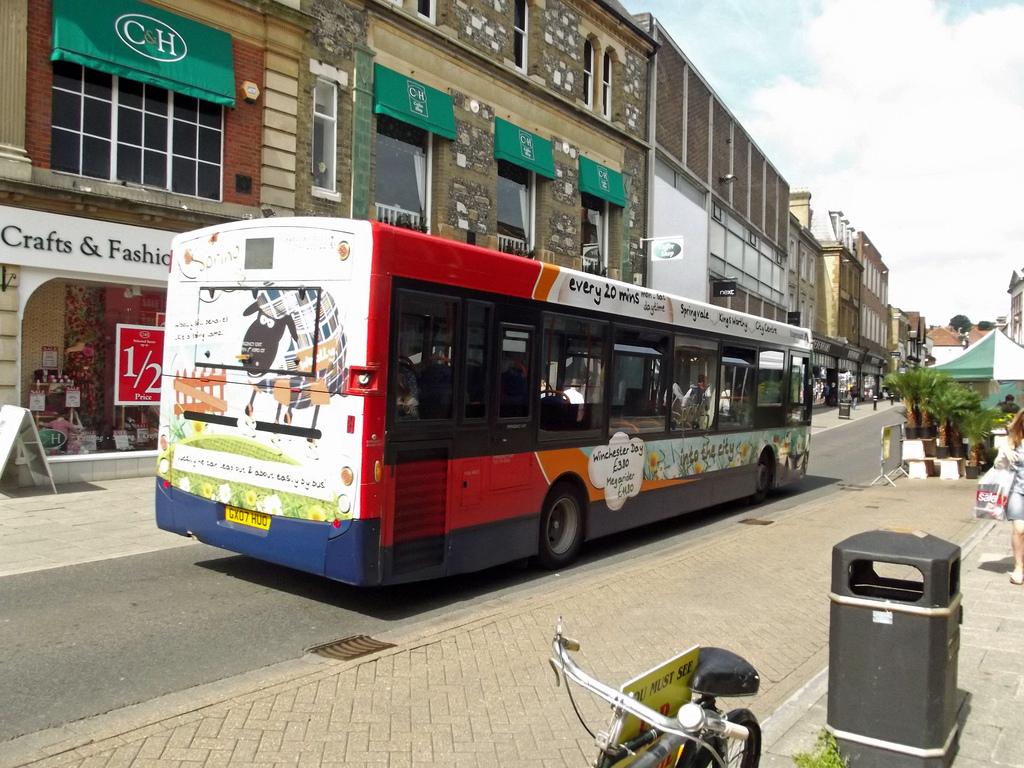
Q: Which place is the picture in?
A: It is at the street.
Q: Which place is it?
A: It is a street.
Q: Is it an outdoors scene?
A: Yes, it is outdoors.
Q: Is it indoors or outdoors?
A: It is outdoors.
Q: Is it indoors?
A: No, it is outdoors.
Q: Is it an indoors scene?
A: No, it is outdoors.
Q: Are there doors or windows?
A: Yes, there are windows.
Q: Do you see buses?
A: Yes, there is a bus.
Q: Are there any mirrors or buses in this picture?
A: Yes, there is a bus.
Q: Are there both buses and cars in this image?
A: No, there is a bus but no cars.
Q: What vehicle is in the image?
A: The vehicle is a bus.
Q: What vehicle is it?
A: The vehicle is a bus.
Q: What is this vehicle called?
A: This is a bus.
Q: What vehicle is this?
A: This is a bus.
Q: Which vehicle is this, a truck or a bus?
A: This is a bus.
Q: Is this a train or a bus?
A: This is a bus.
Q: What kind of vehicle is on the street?
A: The vehicle is a bus.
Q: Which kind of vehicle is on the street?
A: The vehicle is a bus.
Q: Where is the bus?
A: The bus is on the street.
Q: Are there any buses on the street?
A: Yes, there is a bus on the street.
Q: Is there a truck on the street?
A: No, there is a bus on the street.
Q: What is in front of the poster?
A: The bus is in front of the poster.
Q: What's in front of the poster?
A: The bus is in front of the poster.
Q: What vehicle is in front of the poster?
A: The vehicle is a bus.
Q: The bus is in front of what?
A: The bus is in front of the poster.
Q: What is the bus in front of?
A: The bus is in front of the poster.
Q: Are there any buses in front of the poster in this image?
A: Yes, there is a bus in front of the poster.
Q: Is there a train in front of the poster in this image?
A: No, there is a bus in front of the poster.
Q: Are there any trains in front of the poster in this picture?
A: No, there is a bus in front of the poster.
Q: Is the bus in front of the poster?
A: Yes, the bus is in front of the poster.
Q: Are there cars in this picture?
A: No, there are no cars.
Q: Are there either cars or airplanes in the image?
A: No, there are no cars or airplanes.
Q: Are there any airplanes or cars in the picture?
A: No, there are no cars or airplanes.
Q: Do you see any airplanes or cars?
A: No, there are no cars or airplanes.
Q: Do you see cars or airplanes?
A: No, there are no cars or airplanes.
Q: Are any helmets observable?
A: No, there are no helmets.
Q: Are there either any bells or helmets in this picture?
A: No, there are no helmets or bells.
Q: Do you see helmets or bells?
A: No, there are no helmets or bells.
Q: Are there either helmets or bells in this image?
A: No, there are no helmets or bells.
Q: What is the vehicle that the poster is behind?
A: The vehicle is a bus.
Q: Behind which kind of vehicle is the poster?
A: The poster is behind the bus.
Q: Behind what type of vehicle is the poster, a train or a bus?
A: The poster is behind a bus.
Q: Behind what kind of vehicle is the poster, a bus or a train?
A: The poster is behind a bus.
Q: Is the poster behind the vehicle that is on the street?
A: Yes, the poster is behind the bus.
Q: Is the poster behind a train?
A: No, the poster is behind the bus.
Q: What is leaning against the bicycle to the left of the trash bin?
A: The sign is leaning against the bicycle.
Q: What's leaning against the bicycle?
A: The sign is leaning against the bicycle.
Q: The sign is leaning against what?
A: The sign is leaning against the bicycle.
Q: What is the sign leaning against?
A: The sign is leaning against the bicycle.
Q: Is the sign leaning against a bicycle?
A: Yes, the sign is leaning against a bicycle.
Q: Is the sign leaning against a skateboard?
A: No, the sign is leaning against a bicycle.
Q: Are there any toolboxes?
A: No, there are no toolboxes.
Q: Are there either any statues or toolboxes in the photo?
A: No, there are no toolboxes or statues.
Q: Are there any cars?
A: No, there are no cars.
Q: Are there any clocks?
A: No, there are no clocks.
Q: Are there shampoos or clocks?
A: No, there are no clocks or shampoos.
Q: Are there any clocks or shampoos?
A: No, there are no clocks or shampoos.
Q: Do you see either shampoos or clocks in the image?
A: No, there are no clocks or shampoos.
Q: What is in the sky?
A: The clouds are in the sky.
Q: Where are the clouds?
A: The clouds are in the sky.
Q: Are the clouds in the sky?
A: Yes, the clouds are in the sky.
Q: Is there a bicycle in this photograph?
A: Yes, there is a bicycle.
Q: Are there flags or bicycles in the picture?
A: Yes, there is a bicycle.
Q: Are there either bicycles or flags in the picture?
A: Yes, there is a bicycle.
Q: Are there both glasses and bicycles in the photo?
A: No, there is a bicycle but no glasses.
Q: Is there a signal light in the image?
A: No, there are no traffic lights.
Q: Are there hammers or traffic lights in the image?
A: No, there are no traffic lights or hammers.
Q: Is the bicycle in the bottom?
A: Yes, the bicycle is in the bottom of the image.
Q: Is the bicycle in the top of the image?
A: No, the bicycle is in the bottom of the image.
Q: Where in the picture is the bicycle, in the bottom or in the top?
A: The bicycle is in the bottom of the image.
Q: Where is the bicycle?
A: The bicycle is on the sidewalk.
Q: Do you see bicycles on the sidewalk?
A: Yes, there is a bicycle on the sidewalk.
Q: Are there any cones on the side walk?
A: No, there is a bicycle on the side walk.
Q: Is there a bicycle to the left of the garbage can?
A: Yes, there is a bicycle to the left of the garbage can.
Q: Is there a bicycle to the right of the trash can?
A: No, the bicycle is to the left of the trash can.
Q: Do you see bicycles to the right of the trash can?
A: No, the bicycle is to the left of the trash can.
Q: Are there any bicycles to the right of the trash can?
A: No, the bicycle is to the left of the trash can.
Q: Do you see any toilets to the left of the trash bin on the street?
A: No, there is a bicycle to the left of the trash can.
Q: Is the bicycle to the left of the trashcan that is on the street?
A: Yes, the bicycle is to the left of the trash bin.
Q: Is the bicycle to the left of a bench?
A: No, the bicycle is to the left of the trash bin.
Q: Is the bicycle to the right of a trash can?
A: No, the bicycle is to the left of a trash can.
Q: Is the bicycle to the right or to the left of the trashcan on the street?
A: The bicycle is to the left of the garbage can.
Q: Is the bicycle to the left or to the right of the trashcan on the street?
A: The bicycle is to the left of the garbage can.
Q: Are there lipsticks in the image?
A: No, there are no lipsticks.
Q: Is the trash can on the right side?
A: Yes, the trash can is on the right of the image.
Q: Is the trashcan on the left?
A: No, the trashcan is on the right of the image.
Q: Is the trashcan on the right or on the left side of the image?
A: The trashcan is on the right of the image.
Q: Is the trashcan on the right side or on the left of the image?
A: The trashcan is on the right of the image.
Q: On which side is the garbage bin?
A: The garbage bin is on the right of the image.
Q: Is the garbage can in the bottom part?
A: Yes, the garbage can is in the bottom of the image.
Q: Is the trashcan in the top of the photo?
A: No, the trashcan is in the bottom of the image.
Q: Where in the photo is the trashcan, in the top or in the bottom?
A: The trashcan is in the bottom of the image.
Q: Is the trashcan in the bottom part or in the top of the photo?
A: The trashcan is in the bottom of the image.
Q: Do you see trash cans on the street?
A: Yes, there is a trash can on the street.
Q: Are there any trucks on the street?
A: No, there is a trash can on the street.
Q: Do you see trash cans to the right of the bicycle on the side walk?
A: Yes, there is a trash can to the right of the bicycle.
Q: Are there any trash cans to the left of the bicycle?
A: No, the trash can is to the right of the bicycle.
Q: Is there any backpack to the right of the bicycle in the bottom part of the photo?
A: No, there is a trash can to the right of the bicycle.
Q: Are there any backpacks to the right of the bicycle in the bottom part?
A: No, there is a trash can to the right of the bicycle.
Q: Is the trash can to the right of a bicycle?
A: Yes, the trash can is to the right of a bicycle.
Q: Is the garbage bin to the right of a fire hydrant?
A: No, the garbage bin is to the right of a bicycle.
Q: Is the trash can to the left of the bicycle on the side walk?
A: No, the trash can is to the right of the bicycle.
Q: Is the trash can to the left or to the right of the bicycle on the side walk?
A: The trash can is to the right of the bicycle.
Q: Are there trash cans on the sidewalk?
A: Yes, there is a trash can on the sidewalk.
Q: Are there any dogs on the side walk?
A: No, there is a trash can on the side walk.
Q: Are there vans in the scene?
A: No, there are no vans.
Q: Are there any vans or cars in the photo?
A: No, there are no vans or cars.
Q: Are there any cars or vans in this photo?
A: No, there are no vans or cars.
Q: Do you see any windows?
A: Yes, there is a window.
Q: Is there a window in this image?
A: Yes, there is a window.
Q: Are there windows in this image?
A: Yes, there is a window.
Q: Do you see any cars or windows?
A: Yes, there is a window.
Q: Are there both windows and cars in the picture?
A: No, there is a window but no cars.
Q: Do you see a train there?
A: No, there are no trains.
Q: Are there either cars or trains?
A: No, there are no trains or cars.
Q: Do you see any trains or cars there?
A: No, there are no trains or cars.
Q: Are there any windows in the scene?
A: Yes, there is a window.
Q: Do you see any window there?
A: Yes, there is a window.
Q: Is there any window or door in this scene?
A: Yes, there is a window.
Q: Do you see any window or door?
A: Yes, there is a window.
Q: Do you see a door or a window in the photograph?
A: Yes, there is a window.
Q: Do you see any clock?
A: No, there are no clocks.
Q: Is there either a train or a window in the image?
A: Yes, there is a window.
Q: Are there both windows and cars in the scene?
A: No, there is a window but no cars.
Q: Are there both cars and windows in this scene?
A: No, there is a window but no cars.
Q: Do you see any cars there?
A: No, there are no cars.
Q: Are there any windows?
A: Yes, there is a window.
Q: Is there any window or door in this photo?
A: Yes, there is a window.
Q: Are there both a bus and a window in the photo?
A: Yes, there are both a window and a bus.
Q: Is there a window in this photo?
A: Yes, there is a window.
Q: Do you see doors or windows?
A: Yes, there is a window.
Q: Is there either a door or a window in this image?
A: Yes, there is a window.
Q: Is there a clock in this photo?
A: No, there are no clocks.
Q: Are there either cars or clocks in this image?
A: No, there are no clocks or cars.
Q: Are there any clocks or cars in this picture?
A: No, there are no clocks or cars.